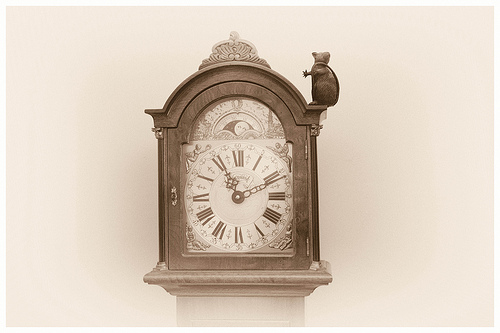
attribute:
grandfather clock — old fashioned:
[133, 40, 348, 276]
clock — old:
[139, 29, 342, 302]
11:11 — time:
[206, 142, 294, 214]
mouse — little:
[301, 50, 341, 108]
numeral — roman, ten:
[195, 169, 215, 184]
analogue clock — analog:
[184, 96, 293, 256]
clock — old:
[175, 87, 302, 241]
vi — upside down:
[234, 225, 244, 242]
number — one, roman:
[249, 151, 264, 172]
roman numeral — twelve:
[231, 146, 248, 168]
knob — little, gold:
[166, 184, 178, 208]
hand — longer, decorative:
[235, 163, 287, 202]